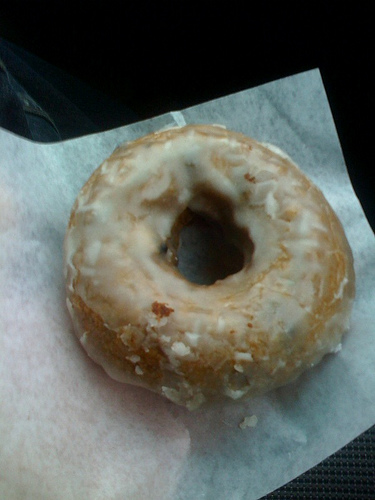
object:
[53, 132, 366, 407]
donut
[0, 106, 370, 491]
paper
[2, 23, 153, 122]
jeans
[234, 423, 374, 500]
seat